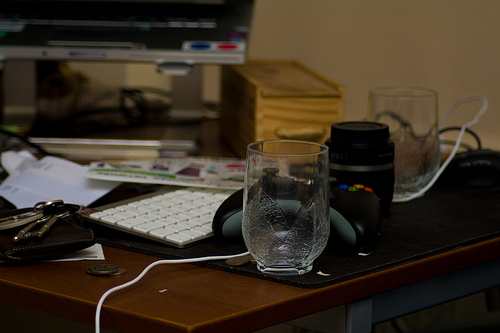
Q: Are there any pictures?
A: No, there are no pictures.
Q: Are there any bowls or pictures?
A: No, there are no pictures or bowls.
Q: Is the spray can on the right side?
A: Yes, the spray can is on the right of the image.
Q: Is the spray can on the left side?
A: No, the spray can is on the right of the image.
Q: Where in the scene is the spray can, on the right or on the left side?
A: The spray can is on the right of the image.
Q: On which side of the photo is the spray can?
A: The spray can is on the right of the image.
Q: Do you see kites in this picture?
A: No, there are no kites.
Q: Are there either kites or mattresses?
A: No, there are no kites or mattresses.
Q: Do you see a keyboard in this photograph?
A: Yes, there is a keyboard.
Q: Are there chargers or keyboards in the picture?
A: Yes, there is a keyboard.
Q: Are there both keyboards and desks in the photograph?
A: Yes, there are both a keyboard and a desk.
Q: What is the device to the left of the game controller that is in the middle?
A: The device is a keyboard.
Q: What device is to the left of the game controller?
A: The device is a keyboard.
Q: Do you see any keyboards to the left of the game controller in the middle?
A: Yes, there is a keyboard to the left of the game controller.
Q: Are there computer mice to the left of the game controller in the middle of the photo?
A: No, there is a keyboard to the left of the game controller.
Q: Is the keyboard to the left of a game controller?
A: Yes, the keyboard is to the left of a game controller.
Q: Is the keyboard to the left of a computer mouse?
A: No, the keyboard is to the left of a game controller.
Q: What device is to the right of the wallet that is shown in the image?
A: The device is a keyboard.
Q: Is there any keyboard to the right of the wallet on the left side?
A: Yes, there is a keyboard to the right of the wallet.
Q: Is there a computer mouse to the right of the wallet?
A: No, there is a keyboard to the right of the wallet.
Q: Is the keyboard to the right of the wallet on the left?
A: Yes, the keyboard is to the right of the wallet.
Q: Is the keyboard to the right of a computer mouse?
A: No, the keyboard is to the right of the wallet.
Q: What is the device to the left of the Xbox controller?
A: The device is a keyboard.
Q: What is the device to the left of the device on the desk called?
A: The device is a keyboard.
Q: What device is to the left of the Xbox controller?
A: The device is a keyboard.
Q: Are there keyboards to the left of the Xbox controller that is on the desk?
A: Yes, there is a keyboard to the left of the Xbox controller.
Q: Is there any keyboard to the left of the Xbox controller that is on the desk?
A: Yes, there is a keyboard to the left of the Xbox controller.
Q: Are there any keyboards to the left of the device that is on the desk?
A: Yes, there is a keyboard to the left of the Xbox controller.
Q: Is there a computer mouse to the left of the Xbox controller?
A: No, there is a keyboard to the left of the Xbox controller.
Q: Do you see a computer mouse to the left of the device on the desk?
A: No, there is a keyboard to the left of the Xbox controller.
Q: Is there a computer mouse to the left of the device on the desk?
A: No, there is a keyboard to the left of the Xbox controller.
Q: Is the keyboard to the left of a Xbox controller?
A: Yes, the keyboard is to the left of a Xbox controller.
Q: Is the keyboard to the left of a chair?
A: No, the keyboard is to the left of a Xbox controller.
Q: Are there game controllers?
A: Yes, there is a game controller.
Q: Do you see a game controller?
A: Yes, there is a game controller.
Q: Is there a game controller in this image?
A: Yes, there is a game controller.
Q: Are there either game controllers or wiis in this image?
A: Yes, there is a game controller.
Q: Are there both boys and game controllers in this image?
A: No, there is a game controller but no boys.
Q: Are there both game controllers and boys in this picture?
A: No, there is a game controller but no boys.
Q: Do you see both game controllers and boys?
A: No, there is a game controller but no boys.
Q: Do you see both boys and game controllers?
A: No, there is a game controller but no boys.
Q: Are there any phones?
A: No, there are no phones.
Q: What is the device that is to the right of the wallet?
A: The device is a game controller.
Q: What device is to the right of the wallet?
A: The device is a game controller.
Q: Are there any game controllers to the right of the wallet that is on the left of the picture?
A: Yes, there is a game controller to the right of the wallet.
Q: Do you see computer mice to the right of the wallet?
A: No, there is a game controller to the right of the wallet.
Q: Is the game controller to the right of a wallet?
A: Yes, the game controller is to the right of a wallet.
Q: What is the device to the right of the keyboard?
A: The device is a game controller.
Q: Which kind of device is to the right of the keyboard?
A: The device is a game controller.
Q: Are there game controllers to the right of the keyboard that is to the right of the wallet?
A: Yes, there is a game controller to the right of the keyboard.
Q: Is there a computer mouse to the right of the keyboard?
A: No, there is a game controller to the right of the keyboard.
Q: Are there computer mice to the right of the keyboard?
A: No, there is a game controller to the right of the keyboard.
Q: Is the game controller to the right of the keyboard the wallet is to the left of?
A: Yes, the game controller is to the right of the keyboard.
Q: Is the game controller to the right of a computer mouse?
A: No, the game controller is to the right of the keyboard.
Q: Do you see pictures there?
A: No, there are no pictures.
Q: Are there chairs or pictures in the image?
A: No, there are no pictures or chairs.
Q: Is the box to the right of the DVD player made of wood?
A: Yes, the box is made of wood.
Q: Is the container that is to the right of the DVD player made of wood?
A: Yes, the box is made of wood.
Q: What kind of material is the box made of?
A: The box is made of wood.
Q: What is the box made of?
A: The box is made of wood.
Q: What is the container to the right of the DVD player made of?
A: The box is made of wood.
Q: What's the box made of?
A: The box is made of wood.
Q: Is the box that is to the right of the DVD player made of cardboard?
A: No, the box is made of wood.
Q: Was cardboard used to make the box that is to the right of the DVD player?
A: No, the box is made of wood.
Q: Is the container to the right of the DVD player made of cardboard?
A: No, the box is made of wood.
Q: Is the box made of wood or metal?
A: The box is made of wood.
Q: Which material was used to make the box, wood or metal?
A: The box is made of wood.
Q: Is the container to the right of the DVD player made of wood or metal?
A: The box is made of wood.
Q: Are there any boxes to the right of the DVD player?
A: Yes, there is a box to the right of the DVD player.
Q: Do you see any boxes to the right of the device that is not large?
A: Yes, there is a box to the right of the DVD player.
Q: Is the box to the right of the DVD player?
A: Yes, the box is to the right of the DVD player.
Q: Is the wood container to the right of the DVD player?
A: Yes, the box is to the right of the DVD player.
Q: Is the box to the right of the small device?
A: Yes, the box is to the right of the DVD player.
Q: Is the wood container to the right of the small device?
A: Yes, the box is to the right of the DVD player.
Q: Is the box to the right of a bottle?
A: No, the box is to the right of the DVD player.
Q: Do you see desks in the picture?
A: Yes, there is a desk.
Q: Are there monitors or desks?
A: Yes, there is a desk.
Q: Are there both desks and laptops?
A: No, there is a desk but no laptops.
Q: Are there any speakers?
A: No, there are no speakers.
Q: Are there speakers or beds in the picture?
A: No, there are no speakers or beds.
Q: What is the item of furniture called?
A: The piece of furniture is a desk.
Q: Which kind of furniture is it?
A: The piece of furniture is a desk.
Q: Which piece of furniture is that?
A: That is a desk.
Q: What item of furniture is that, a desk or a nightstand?
A: That is a desk.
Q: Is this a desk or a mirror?
A: This is a desk.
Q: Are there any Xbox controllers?
A: Yes, there is a Xbox controller.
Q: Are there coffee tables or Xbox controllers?
A: Yes, there is a Xbox controller.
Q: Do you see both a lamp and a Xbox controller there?
A: No, there is a Xbox controller but no lamps.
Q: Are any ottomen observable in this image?
A: No, there are no ottomen.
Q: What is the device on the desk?
A: The device is a Xbox controller.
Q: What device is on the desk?
A: The device is a Xbox controller.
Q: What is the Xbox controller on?
A: The Xbox controller is on the desk.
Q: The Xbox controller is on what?
A: The Xbox controller is on the desk.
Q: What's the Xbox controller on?
A: The Xbox controller is on the desk.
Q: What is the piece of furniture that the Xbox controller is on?
A: The piece of furniture is a desk.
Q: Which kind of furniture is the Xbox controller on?
A: The Xbox controller is on the desk.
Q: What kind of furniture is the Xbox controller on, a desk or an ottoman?
A: The Xbox controller is on a desk.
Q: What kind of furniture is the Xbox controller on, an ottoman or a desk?
A: The Xbox controller is on a desk.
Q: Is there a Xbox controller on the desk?
A: Yes, there is a Xbox controller on the desk.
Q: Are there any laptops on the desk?
A: No, there is a Xbox controller on the desk.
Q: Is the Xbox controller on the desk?
A: Yes, the Xbox controller is on the desk.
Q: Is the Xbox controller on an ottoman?
A: No, the Xbox controller is on the desk.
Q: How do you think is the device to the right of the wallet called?
A: The device is a Xbox controller.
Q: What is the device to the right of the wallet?
A: The device is a Xbox controller.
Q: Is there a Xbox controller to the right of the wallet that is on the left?
A: Yes, there is a Xbox controller to the right of the wallet.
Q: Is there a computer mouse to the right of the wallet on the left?
A: No, there is a Xbox controller to the right of the wallet.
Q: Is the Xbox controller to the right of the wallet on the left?
A: Yes, the Xbox controller is to the right of the wallet.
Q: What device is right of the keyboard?
A: The device is a Xbox controller.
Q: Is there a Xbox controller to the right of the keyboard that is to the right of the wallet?
A: Yes, there is a Xbox controller to the right of the keyboard.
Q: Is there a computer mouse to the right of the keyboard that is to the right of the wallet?
A: No, there is a Xbox controller to the right of the keyboard.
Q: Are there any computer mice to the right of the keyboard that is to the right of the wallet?
A: No, there is a Xbox controller to the right of the keyboard.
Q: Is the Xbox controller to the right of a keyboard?
A: Yes, the Xbox controller is to the right of a keyboard.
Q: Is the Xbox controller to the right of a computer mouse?
A: No, the Xbox controller is to the right of a keyboard.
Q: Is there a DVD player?
A: Yes, there is a DVD player.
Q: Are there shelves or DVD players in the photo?
A: Yes, there is a DVD player.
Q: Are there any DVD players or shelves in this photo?
A: Yes, there is a DVD player.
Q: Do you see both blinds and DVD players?
A: No, there is a DVD player but no blinds.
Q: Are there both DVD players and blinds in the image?
A: No, there is a DVD player but no blinds.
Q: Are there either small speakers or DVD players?
A: Yes, there is a small DVD player.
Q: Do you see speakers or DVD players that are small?
A: Yes, the DVD player is small.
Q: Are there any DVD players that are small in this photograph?
A: Yes, there is a small DVD player.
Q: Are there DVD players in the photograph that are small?
A: Yes, there is a DVD player that is small.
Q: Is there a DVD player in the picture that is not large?
A: Yes, there is a small DVD player.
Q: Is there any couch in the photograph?
A: No, there are no couches.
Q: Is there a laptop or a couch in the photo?
A: No, there are no couches or laptops.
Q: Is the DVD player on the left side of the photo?
A: Yes, the DVD player is on the left of the image.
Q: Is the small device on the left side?
A: Yes, the DVD player is on the left of the image.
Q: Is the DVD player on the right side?
A: No, the DVD player is on the left of the image.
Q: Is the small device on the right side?
A: No, the DVD player is on the left of the image.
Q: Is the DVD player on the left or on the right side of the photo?
A: The DVD player is on the left of the image.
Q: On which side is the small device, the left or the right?
A: The DVD player is on the left of the image.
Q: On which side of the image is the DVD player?
A: The DVD player is on the left of the image.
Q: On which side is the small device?
A: The DVD player is on the left of the image.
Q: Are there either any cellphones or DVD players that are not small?
A: No, there is a DVD player but it is small.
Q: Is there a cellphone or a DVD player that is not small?
A: No, there is a DVD player but it is small.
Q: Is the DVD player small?
A: Yes, the DVD player is small.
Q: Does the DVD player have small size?
A: Yes, the DVD player is small.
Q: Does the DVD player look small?
A: Yes, the DVD player is small.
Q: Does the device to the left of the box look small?
A: Yes, the DVD player is small.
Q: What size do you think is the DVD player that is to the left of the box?
A: The DVD player is small.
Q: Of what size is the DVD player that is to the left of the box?
A: The DVD player is small.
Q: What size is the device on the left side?
A: The DVD player is small.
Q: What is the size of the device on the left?
A: The DVD player is small.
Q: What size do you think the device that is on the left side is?
A: The DVD player is small.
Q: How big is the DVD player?
A: The DVD player is small.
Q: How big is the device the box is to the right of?
A: The DVD player is small.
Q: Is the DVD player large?
A: No, the DVD player is small.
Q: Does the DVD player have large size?
A: No, the DVD player is small.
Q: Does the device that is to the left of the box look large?
A: No, the DVD player is small.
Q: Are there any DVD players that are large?
A: No, there is a DVD player but it is small.